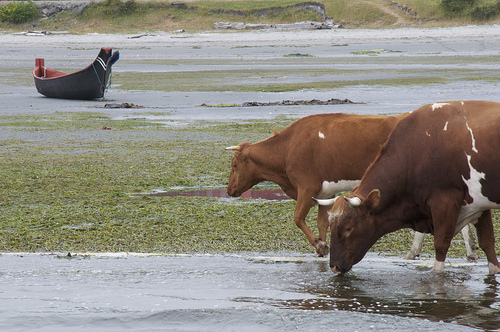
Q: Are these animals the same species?
A: Yes, all the animals are cows.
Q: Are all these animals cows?
A: Yes, all the animals are cows.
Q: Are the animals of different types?
A: No, all the animals are cows.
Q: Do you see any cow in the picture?
A: Yes, there is a cow.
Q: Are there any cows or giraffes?
A: Yes, there is a cow.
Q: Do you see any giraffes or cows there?
A: Yes, there is a cow.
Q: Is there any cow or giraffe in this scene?
A: Yes, there is a cow.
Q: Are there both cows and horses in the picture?
A: No, there is a cow but no horses.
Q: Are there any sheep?
A: No, there are no sheep.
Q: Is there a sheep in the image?
A: No, there is no sheep.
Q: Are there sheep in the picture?
A: No, there are no sheep.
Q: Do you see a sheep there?
A: No, there is no sheep.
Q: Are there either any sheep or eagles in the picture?
A: No, there are no sheep or eagles.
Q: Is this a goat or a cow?
A: This is a cow.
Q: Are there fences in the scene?
A: No, there are no fences.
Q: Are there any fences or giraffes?
A: No, there are no fences or giraffes.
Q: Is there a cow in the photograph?
A: Yes, there is a cow.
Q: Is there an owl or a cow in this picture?
A: Yes, there is a cow.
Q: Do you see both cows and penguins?
A: No, there is a cow but no penguins.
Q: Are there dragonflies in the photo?
A: No, there are no dragonflies.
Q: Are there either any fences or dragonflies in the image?
A: No, there are no dragonflies or fences.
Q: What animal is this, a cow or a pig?
A: This is a cow.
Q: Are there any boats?
A: Yes, there is a boat.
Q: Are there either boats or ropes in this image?
A: Yes, there is a boat.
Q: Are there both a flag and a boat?
A: No, there is a boat but no flags.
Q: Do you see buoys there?
A: No, there are no buoys.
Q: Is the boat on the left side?
A: Yes, the boat is on the left of the image.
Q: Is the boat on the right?
A: No, the boat is on the left of the image.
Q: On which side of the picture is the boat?
A: The boat is on the left of the image.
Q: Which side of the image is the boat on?
A: The boat is on the left of the image.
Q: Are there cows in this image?
A: Yes, there are cows.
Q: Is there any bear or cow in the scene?
A: Yes, there are cows.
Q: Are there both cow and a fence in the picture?
A: No, there are cows but no fences.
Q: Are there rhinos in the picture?
A: No, there are no rhinos.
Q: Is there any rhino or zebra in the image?
A: No, there are no rhinos or zebras.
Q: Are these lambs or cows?
A: These are cows.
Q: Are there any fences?
A: No, there are no fences.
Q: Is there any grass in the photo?
A: Yes, there is grass.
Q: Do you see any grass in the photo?
A: Yes, there is grass.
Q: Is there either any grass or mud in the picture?
A: Yes, there is grass.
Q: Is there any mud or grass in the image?
A: Yes, there is grass.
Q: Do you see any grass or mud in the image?
A: Yes, there is grass.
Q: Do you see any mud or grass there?
A: Yes, there is grass.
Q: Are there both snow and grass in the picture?
A: No, there is grass but no snow.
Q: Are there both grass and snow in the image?
A: No, there is grass but no snow.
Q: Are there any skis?
A: No, there are no skis.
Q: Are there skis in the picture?
A: No, there are no skis.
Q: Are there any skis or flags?
A: No, there are no skis or flags.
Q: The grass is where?
A: The grass is on the ground.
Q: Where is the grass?
A: The grass is on the ground.